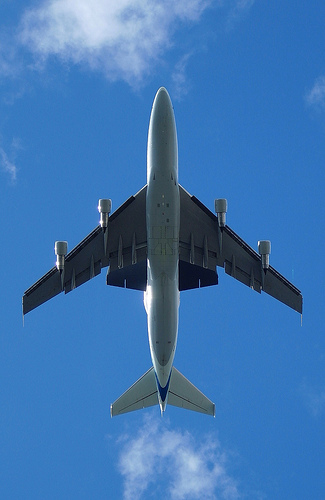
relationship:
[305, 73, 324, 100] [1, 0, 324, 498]
clouds in sky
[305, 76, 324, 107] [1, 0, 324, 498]
clouds in sky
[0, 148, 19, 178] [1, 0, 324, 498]
clouds in sky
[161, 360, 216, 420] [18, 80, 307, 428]
tail wing of an airplane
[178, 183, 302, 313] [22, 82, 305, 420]
wing of a airplane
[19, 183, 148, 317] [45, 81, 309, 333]
tail wing on plane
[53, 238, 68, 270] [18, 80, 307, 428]
engine on airplane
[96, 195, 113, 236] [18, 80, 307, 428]
engine on airplane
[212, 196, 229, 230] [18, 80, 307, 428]
engine on airplane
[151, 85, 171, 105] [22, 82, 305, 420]
nose on airplane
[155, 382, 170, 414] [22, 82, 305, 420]
tail on airplane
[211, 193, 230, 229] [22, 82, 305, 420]
engine on airplane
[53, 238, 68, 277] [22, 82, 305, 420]
engine on airplane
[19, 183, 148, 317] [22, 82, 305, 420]
tail wing on airplane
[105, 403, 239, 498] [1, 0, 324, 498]
clouds in sky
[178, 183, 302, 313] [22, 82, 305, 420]
wing on airplane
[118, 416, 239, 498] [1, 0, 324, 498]
clouds in sky